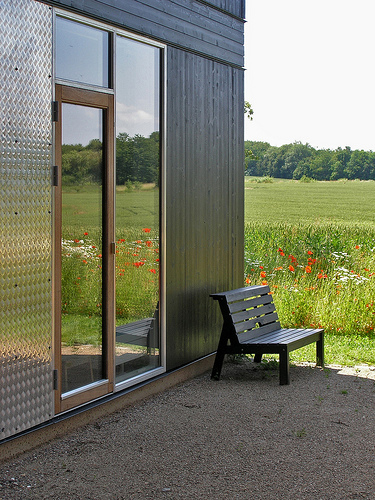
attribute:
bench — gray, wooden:
[210, 282, 328, 378]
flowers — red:
[251, 243, 357, 304]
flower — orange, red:
[287, 264, 296, 272]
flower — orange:
[306, 249, 314, 256]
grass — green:
[245, 227, 374, 366]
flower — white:
[291, 286, 301, 294]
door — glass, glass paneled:
[54, 86, 114, 415]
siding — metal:
[2, 1, 53, 446]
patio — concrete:
[2, 361, 374, 497]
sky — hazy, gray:
[245, 0, 372, 149]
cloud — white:
[115, 100, 153, 135]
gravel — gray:
[2, 364, 372, 494]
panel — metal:
[1, 0, 55, 439]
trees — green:
[245, 139, 374, 183]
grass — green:
[245, 179, 374, 226]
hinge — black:
[51, 101, 60, 124]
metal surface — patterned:
[2, 3, 55, 442]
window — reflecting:
[115, 32, 170, 392]